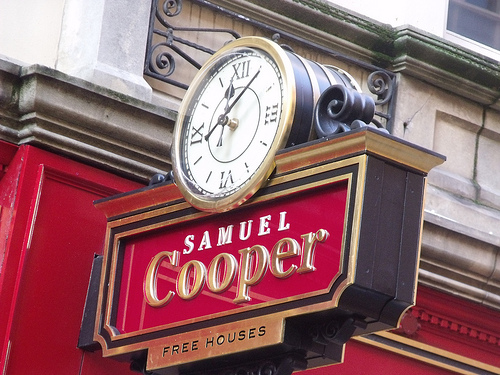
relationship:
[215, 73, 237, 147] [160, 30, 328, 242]
hand on clock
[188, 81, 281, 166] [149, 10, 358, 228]
face on clock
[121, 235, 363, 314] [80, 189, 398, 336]
word on sign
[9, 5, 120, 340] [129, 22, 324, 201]
building near clock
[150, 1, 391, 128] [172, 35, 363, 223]
iron behind clock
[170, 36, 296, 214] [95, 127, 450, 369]
clock on sign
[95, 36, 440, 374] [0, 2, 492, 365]
sign attached to wall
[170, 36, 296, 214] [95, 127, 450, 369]
clock above sign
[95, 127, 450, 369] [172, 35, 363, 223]
sign below clock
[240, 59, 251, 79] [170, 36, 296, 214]
numbers on clock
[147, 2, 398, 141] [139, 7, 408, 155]
bars over window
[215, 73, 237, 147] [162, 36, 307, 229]
hand on clock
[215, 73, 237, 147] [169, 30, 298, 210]
hand on clock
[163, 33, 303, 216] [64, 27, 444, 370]
clock on sign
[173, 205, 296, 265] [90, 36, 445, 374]
word on sign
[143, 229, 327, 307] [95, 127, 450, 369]
word on sign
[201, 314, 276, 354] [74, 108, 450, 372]
word on sign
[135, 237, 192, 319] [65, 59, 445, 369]
c on sign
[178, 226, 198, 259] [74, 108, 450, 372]
s on sign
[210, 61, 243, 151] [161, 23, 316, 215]
hand on clock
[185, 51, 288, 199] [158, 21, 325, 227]
numbers on clock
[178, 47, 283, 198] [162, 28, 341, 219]
face on clock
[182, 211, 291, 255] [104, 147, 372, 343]
word on sign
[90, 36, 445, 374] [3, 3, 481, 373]
sign attached to building